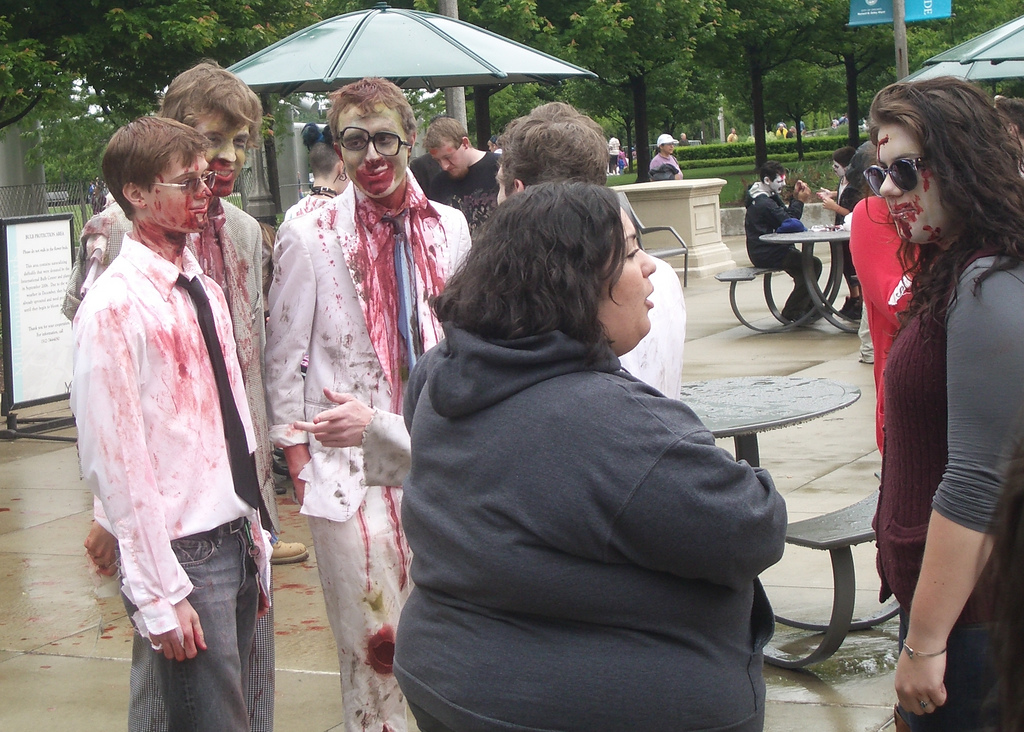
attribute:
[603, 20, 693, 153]
leaves — green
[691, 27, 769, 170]
leaves — green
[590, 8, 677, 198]
leaves — green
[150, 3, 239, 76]
leaves — green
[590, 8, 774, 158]
leaves — green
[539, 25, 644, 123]
leaves — green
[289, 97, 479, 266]
paint — green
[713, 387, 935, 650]
table — gray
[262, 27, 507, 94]
umbrella — green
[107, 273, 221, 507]
tie — black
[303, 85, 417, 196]
glasses — black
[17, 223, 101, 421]
sign — black, white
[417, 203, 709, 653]
hoodie — charcoal gray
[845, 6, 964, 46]
signs — blue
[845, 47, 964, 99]
pole — flag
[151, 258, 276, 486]
tie — black, neck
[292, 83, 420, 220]
makeup — theatrical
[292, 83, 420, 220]
glasses — crocked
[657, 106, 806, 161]
people — caucasian, yellow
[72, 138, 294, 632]
shirt — white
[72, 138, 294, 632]
stains — red